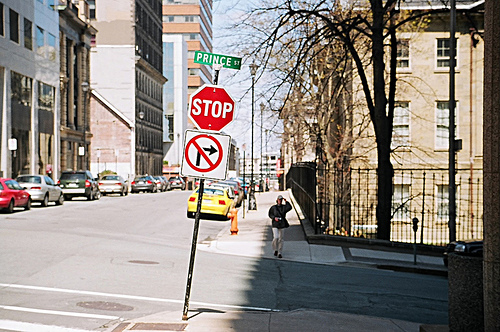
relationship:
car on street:
[187, 186, 233, 219] [2, 178, 254, 327]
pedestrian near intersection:
[267, 194, 294, 259] [0, 213, 211, 295]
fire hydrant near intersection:
[224, 205, 242, 236] [0, 213, 211, 295]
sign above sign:
[194, 48, 241, 72] [190, 83, 235, 133]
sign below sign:
[190, 83, 235, 133] [194, 48, 241, 72]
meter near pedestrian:
[412, 216, 418, 267] [267, 194, 294, 259]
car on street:
[0, 175, 32, 214] [2, 178, 254, 327]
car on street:
[12, 174, 63, 206] [2, 178, 254, 327]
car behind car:
[0, 175, 32, 214] [12, 174, 63, 206]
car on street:
[59, 172, 97, 203] [2, 178, 254, 327]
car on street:
[97, 175, 129, 194] [2, 178, 254, 327]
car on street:
[132, 171, 156, 194] [2, 178, 254, 327]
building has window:
[318, 7, 484, 242] [436, 36, 458, 73]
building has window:
[318, 7, 484, 242] [387, 39, 412, 75]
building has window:
[318, 7, 484, 242] [437, 101, 456, 149]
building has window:
[318, 7, 484, 242] [381, 102, 408, 157]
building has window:
[318, 7, 484, 242] [436, 183, 458, 222]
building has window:
[318, 7, 484, 242] [390, 184, 413, 221]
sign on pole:
[190, 83, 235, 133] [184, 73, 219, 323]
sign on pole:
[194, 48, 241, 72] [184, 73, 219, 323]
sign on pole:
[183, 130, 230, 182] [184, 73, 219, 323]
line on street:
[2, 278, 281, 314] [2, 178, 254, 327]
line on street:
[0, 300, 120, 324] [2, 178, 254, 327]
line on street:
[0, 316, 92, 332] [2, 178, 254, 327]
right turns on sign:
[192, 142, 222, 167] [179, 129, 231, 183]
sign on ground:
[189, 46, 246, 71] [0, 163, 495, 330]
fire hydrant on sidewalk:
[224, 203, 242, 235] [207, 186, 451, 275]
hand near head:
[281, 187, 289, 203] [269, 184, 291, 213]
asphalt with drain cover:
[7, 184, 464, 331] [77, 297, 137, 308]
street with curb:
[4, 190, 498, 326] [215, 200, 497, 280]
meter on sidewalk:
[411, 216, 421, 265] [341, 246, 407, 269]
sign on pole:
[185, 83, 238, 133] [184, 174, 213, 323]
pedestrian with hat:
[267, 194, 294, 259] [276, 192, 288, 203]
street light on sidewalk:
[245, 57, 262, 211] [210, 189, 313, 264]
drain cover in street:
[126, 258, 162, 265] [0, 177, 484, 330]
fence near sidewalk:
[281, 155, 316, 233] [210, 189, 313, 264]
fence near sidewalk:
[316, 165, 482, 245] [307, 236, 448, 272]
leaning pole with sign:
[166, 31, 248, 325] [190, 48, 245, 70]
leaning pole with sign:
[166, 31, 248, 325] [185, 83, 238, 133]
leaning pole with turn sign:
[166, 31, 248, 325] [177, 123, 232, 188]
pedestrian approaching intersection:
[267, 194, 294, 259] [0, 213, 211, 330]